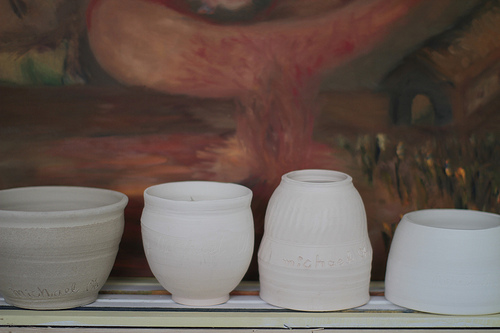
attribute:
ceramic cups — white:
[140, 169, 497, 311]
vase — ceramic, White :
[384, 207, 499, 315]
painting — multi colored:
[5, 0, 499, 288]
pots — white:
[271, 177, 495, 328]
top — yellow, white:
[0, 275, 499, 327]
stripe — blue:
[95, 286, 385, 298]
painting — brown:
[8, 0, 498, 187]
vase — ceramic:
[2, 185, 128, 312]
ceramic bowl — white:
[3, 184, 130, 312]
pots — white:
[67, 162, 498, 309]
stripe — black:
[1, 324, 499, 331]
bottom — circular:
[282, 161, 357, 193]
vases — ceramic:
[146, 170, 375, 311]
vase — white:
[256, 167, 374, 312]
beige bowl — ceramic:
[0, 185, 125, 309]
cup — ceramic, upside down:
[249, 165, 379, 315]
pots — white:
[255, 170, 367, 310]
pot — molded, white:
[133, 169, 276, 317]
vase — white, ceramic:
[253, 160, 375, 317]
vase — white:
[139, 181, 255, 308]